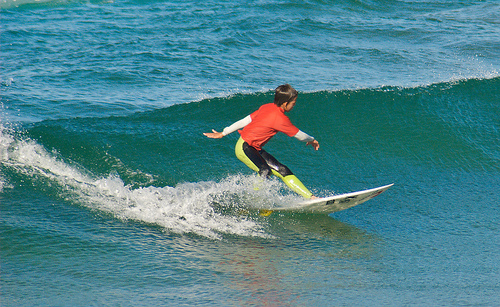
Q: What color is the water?
A: Blue.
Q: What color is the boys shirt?
A: Red.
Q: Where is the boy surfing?
A: The ocean.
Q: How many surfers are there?
A: One.